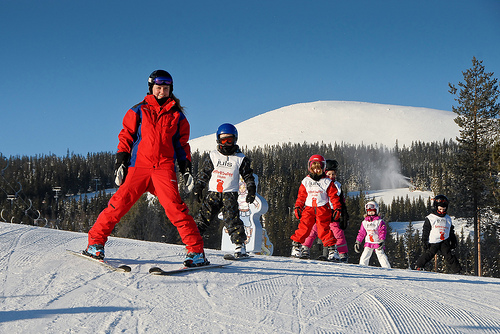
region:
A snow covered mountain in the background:
[240, 79, 440, 163]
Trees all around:
[14, 144, 142, 236]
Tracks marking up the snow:
[264, 274, 425, 332]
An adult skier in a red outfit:
[100, 62, 221, 279]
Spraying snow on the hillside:
[359, 146, 438, 192]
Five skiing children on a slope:
[192, 116, 467, 263]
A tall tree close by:
[439, 55, 491, 265]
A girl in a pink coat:
[354, 188, 392, 268]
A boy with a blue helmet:
[207, 111, 249, 176]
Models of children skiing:
[209, 165, 295, 268]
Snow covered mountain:
[232, 70, 458, 157]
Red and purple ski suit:
[76, 87, 216, 252]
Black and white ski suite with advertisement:
[195, 140, 265, 255]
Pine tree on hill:
[450, 80, 495, 300]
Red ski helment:
[295, 146, 340, 176]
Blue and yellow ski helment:
[207, 106, 242, 141]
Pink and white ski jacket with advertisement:
[347, 211, 393, 253]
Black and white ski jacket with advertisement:
[420, 210, 468, 255]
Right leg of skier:
[75, 165, 150, 270]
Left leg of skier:
[148, 167, 230, 289]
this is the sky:
[168, 18, 407, 66]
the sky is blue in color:
[256, 19, 368, 49]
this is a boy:
[101, 62, 203, 234]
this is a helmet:
[218, 123, 238, 133]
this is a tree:
[456, 61, 496, 215]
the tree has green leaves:
[458, 148, 468, 192]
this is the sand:
[248, 264, 326, 308]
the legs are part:
[64, 212, 207, 282]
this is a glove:
[183, 172, 194, 194]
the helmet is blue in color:
[218, 123, 232, 131]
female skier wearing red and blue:
[80, 54, 212, 281]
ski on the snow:
[57, 254, 137, 286]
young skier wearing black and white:
[193, 117, 263, 264]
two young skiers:
[288, 152, 347, 260]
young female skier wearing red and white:
[291, 154, 335, 259]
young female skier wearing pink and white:
[353, 193, 396, 273]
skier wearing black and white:
[417, 194, 469, 286]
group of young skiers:
[70, 69, 458, 279]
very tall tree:
[450, 56, 498, 280]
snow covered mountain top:
[236, 98, 453, 141]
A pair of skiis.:
[62, 244, 239, 283]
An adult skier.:
[71, 65, 223, 285]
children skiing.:
[212, 114, 473, 273]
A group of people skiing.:
[66, 54, 465, 284]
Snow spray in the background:
[350, 123, 429, 199]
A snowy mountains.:
[12, 79, 497, 332]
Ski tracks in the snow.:
[28, 277, 489, 332]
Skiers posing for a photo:
[93, 54, 470, 294]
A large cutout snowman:
[215, 170, 272, 267]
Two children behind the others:
[363, 142, 466, 278]